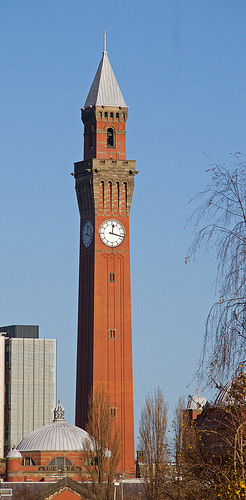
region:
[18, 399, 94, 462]
Silver dome building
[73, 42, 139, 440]
Tower with clocks at the top.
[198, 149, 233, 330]
Leafless tree branches and limbs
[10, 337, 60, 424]
High-rise building.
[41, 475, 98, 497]
Building's roof peak.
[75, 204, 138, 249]
Two turret clocks on top of tower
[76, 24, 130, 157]
Bell tower.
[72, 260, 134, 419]
Three windows in red bell tower.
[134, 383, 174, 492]
Tree without leaves near bell tower.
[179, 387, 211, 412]
Silver dome on top of red building.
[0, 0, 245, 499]
the image is an outside scene of a clock tower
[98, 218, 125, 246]
the clock has a white face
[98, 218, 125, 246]
the time displayed on the clock is 12:17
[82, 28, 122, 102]
the tower has a grey color roof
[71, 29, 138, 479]
the clock tower is built with red bricks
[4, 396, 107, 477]
a round building next to the tower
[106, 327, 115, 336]
a rectangle window is on the side of the building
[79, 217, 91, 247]
a second clock is on the other side of the tower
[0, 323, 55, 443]
a commercial building is near the clock tower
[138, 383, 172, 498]
a deciduous tree stands near the tower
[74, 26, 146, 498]
a very tall building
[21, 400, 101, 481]
a circular design of a bulding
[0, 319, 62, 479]
a tall building to the left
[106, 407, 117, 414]
a window of the building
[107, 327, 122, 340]
a window of the building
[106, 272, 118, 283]
a window of the building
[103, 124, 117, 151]
a window of the building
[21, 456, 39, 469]
a window of the building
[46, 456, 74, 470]
a window of the building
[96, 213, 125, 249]
a clock on the building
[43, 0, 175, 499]
a very tall tower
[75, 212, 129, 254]
two clocks on a tower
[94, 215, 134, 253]
a clock that says 12:17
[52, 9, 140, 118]
a grey ceiling on a tower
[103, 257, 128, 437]
three windows on a brick tower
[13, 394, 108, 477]
a gray colored dome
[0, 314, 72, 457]
a tall building in the background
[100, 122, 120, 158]
a larger window at the top of the tower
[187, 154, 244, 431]
a tree without leabes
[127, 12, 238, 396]
a clear blue sky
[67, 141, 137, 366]
tall red clock tower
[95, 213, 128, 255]
white face on clock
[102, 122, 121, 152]
arched window on tower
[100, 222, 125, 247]
roman numerals on clock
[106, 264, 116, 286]
double windows on tower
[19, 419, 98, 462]
gray dome on building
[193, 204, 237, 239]
tree branches with no leaves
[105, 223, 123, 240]
black hands on clock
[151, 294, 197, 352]
clear blue daytime sky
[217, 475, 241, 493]
yellow leaves on tree